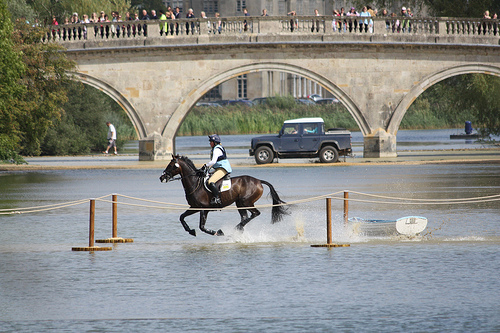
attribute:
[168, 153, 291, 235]
horse — brown, galloping, black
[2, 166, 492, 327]
water — shallow, blue, splashing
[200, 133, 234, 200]
man — riding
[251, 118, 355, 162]
truck — blue, parked, crossing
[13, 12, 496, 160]
bridge — stone arched, long, tall, gray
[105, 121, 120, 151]
man — walking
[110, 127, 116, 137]
shirt — white, short sleeved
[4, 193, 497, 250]
rope course — guide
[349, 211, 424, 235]
boat — white, tiny, blue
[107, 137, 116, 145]
shorts — blue, gray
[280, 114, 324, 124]
top — white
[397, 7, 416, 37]
person — spectating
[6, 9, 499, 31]
people — gathered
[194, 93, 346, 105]
cars — parked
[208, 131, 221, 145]
helmet — dark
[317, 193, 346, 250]
pole — brown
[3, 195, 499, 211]
rope — brown